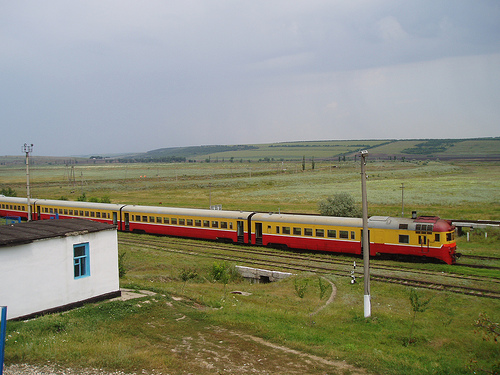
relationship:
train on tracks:
[226, 165, 472, 282] [383, 248, 483, 311]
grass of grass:
[161, 239, 260, 294] [161, 239, 260, 294]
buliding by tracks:
[13, 210, 135, 285] [383, 248, 483, 311]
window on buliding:
[65, 226, 109, 280] [13, 210, 135, 285]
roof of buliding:
[1, 213, 93, 247] [13, 210, 135, 285]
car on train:
[244, 208, 355, 261] [226, 165, 472, 282]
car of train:
[244, 208, 355, 261] [226, 165, 472, 282]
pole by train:
[346, 135, 383, 307] [226, 165, 472, 282]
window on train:
[267, 222, 322, 243] [226, 165, 472, 282]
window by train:
[65, 226, 109, 280] [226, 165, 472, 282]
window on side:
[267, 222, 322, 243] [183, 203, 268, 231]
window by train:
[267, 222, 322, 243] [226, 165, 472, 282]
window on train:
[65, 226, 109, 280] [226, 165, 472, 282]